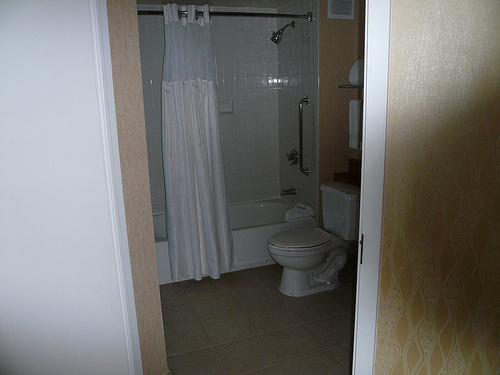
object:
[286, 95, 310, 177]
handle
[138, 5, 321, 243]
shower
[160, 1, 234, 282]
curtain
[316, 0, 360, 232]
wall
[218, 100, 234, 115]
tray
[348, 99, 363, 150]
towel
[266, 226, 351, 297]
toilet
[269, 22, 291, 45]
head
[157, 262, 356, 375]
floor